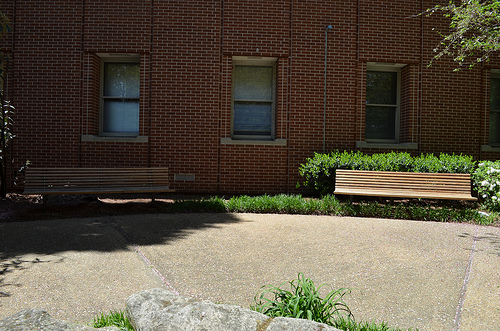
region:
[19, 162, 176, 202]
The bench on the left.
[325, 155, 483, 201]
The bench on the right.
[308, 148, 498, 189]
The bushes behind the bench on the right.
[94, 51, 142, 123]
The window on the left.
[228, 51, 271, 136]
The window in the middle.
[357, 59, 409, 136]
The middle on the right behind the bench.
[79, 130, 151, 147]
The windowsill of the window on the left.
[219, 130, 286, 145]
The windowsill of the window in the middle.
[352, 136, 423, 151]
The windowsill of the window on the right behind the bench.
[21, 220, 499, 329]
The cement area in front of the benches.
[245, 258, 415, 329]
a patch of green grass.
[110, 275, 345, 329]
a large rock near grass.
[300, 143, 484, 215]
a brown bench near grass.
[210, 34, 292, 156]
a window on a brick building.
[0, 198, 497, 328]
a paved walkway.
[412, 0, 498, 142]
a lush green leafy plant.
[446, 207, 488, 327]
a crack in a sidewalk..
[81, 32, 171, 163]
a window on a building.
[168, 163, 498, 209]
grass under a bench.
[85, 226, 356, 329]
grass surrounding a rock.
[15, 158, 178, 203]
A bench in front of a building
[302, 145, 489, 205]
A bench in front of a bush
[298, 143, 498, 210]
A bush behind a bench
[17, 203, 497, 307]
A large sidewalk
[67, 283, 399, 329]
A rock with grass by it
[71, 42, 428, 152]
Three windows on a building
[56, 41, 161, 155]
Brick around a window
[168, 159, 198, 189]
A vent on a building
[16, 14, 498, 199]
A large brick building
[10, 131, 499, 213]
Two benches in front of a building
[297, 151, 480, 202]
wood bench in front of low hedge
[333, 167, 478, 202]
wood bench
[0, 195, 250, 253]
tree shadow on concrete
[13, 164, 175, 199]
wood bench in tree shadow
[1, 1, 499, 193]
red brick building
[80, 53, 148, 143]
sash window above concrete ledge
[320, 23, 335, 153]
metal conduit attached to brick wall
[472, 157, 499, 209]
shrub with white flowers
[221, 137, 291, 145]
concrete window ledge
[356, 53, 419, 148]
sash window with concrete ledge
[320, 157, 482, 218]
brown wooden bench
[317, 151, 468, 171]
bushes growing behind wooden bench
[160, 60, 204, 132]
red bricks on side of building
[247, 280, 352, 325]
grass growing beside path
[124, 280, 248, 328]
large grey rock behind path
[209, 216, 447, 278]
concrete path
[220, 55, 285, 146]
window on side of building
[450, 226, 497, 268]
shadow of leaves on path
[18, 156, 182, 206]
brown wooden bench outside building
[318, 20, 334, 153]
grey metal light on side of building